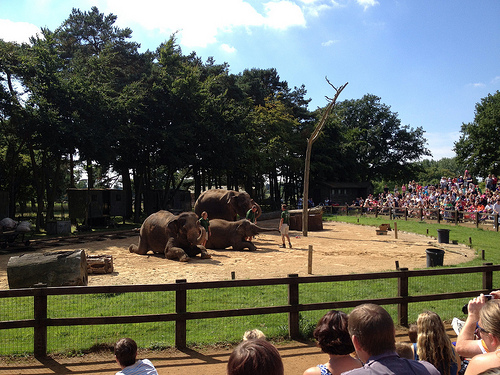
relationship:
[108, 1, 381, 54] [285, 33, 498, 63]
clouds in sky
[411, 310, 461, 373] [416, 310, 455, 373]
woman with hair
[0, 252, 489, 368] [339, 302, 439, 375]
fence front of man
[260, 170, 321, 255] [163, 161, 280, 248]
person standing in front of elephant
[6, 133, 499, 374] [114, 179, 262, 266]
viewers around elephants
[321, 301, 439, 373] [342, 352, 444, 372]
man wearing shirt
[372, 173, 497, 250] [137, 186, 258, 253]
crowd watching elephants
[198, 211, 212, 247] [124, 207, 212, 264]
people elephants near elephant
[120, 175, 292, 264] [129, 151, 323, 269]
people elephants doing show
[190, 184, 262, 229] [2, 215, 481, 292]
elephant in dirt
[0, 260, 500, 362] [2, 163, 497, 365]
fence is on enclosure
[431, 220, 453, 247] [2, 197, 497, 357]
black bin is on enclosure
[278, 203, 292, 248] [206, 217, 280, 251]
person is on elephant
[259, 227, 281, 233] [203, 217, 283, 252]
trunk is on elephant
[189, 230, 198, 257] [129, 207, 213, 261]
trunk is on elephant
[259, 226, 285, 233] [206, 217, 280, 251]
trunk is on elephant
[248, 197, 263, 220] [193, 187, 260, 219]
trunk is on elephant